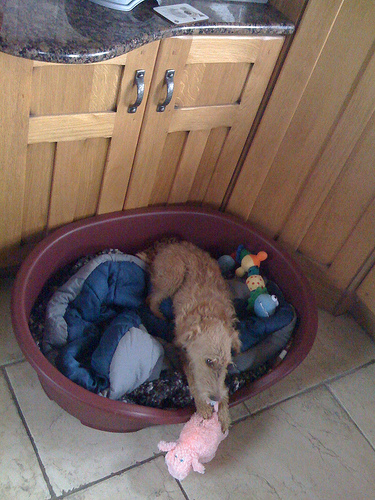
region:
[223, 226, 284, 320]
multi color dog toy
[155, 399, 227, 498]
pink pig dog toy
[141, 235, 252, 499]
brown dog chewing on a toy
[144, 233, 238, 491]
brown dog chewing on a pink toy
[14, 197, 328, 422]
dog in a dog bed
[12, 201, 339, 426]
dog on a blue blanket in a dog bed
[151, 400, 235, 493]
pink toy with blue eyes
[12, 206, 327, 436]
burgundy plastic dog bed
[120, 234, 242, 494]
small brown dog on a blue blanket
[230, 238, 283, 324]
orange and yellow and blue dog toy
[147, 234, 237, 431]
A brown dog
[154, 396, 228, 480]
A pink playtoy for the dog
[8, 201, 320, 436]
A maroon plastic bin the dog sleeps in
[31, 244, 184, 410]
Different types of bedding for the dog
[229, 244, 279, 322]
A stuffed playtoy for the dog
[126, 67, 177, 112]
Metal handles of the cabinet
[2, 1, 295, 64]
a marble counter top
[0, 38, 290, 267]
Wooden cabinet doors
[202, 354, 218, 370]
The eye of the dog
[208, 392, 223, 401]
The black nose of the dog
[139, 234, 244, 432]
scruffy brown terrier mix dog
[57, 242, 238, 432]
brown dog lying on blue comforter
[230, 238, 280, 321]
multicolored caterpillar soft dog toy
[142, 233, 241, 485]
brown dog holding pink sheep stuffed toy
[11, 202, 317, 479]
brown dog in purple plastic dog bed with comforter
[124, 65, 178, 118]
grey metal cabinet handles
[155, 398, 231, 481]
pink sheep stuffed toy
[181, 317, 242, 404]
head of brown terrier dog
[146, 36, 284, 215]
brown wooden cabinet door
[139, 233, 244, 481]
tan dog lying down with stuffed toy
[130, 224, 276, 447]
this is a dog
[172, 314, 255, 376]
the dog is brown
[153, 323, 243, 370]
these are two eyes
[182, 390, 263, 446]
this is a paw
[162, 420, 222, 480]
this is a pig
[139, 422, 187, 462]
the pig is pink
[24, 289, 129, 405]
this is a dog bed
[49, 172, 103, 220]
this is a door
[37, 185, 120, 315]
the door is wooden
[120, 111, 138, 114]
this is a handle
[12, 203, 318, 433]
Brown fluffy dog in a maroon basket.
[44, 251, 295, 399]
Blue and gray blanket inside of the basket.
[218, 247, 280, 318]
Dog toys inside of the basket.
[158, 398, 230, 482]
The dog's paws on a pink toy.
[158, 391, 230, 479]
Dog is chewing on a pink toy.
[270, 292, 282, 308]
Googly eyes on the blue head of a toy.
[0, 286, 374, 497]
Gray marble tile on the floor.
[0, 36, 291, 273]
Brown cupboard doors behind the basket.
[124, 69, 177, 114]
Black metal handles on the doors.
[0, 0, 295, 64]
Brown and blue formica countertop.